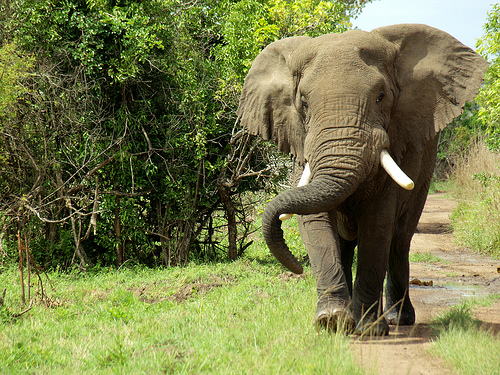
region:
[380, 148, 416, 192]
A tusk on an elephant.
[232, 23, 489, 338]
An elephant in the picture.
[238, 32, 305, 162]
The elephant's right ear.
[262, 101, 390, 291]
The elephant's trunk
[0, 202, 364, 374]
Grass on the ground.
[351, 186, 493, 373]
A dirt path in the wilderness.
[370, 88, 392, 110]
The elephant's left eye.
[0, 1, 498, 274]
Trees and bushes behind the elephant.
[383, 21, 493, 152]
The elephant's left ear.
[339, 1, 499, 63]
A blue sky in the background.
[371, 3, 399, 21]
this is the sky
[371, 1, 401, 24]
the sky is blue in color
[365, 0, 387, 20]
the clouds are white in color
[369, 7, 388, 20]
these are the clouds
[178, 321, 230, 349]
this is the grass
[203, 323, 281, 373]
the grass is green in color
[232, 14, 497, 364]
this is an elephant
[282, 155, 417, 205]
these are the tusks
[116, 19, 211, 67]
these are the trees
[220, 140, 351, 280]
trunk of the elephant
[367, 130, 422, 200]
tusk on the elephant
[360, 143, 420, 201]
white tusk on elephant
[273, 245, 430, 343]
legs on the animal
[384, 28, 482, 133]
ear of the animal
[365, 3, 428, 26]
blue sky above land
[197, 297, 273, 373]
grass under the elephant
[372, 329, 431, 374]
brwn dirt on ground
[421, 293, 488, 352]
shadow on the ground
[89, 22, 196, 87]
leaves on the tree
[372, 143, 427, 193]
white tusk on the elephant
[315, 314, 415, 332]
animal has large feet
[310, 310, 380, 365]
tall blades of grass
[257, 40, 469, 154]
elephant has large ears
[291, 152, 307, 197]
white tusk on the right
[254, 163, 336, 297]
trunk is leaning toward the right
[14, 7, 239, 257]
high green trees to the right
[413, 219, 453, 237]
peice of wood log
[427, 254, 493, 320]
path is filled with dirt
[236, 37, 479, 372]
animal is walking on path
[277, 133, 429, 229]
the tusks are white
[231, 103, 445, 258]
the tusks are white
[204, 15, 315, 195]
elephant's ear is wide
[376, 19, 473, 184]
elephant's ear is wide